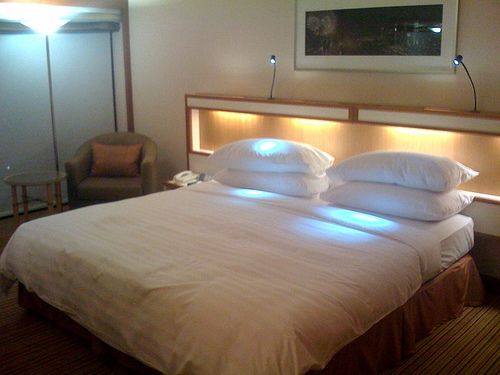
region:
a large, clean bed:
[7, 135, 478, 369]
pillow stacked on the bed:
[204, 135, 477, 220]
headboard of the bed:
[182, 93, 499, 267]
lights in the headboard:
[211, 105, 498, 157]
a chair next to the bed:
[64, 128, 159, 203]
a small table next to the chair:
[3, 168, 66, 219]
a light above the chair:
[20, 16, 72, 35]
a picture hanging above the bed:
[291, 0, 461, 75]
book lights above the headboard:
[266, 51, 481, 112]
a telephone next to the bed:
[171, 170, 198, 185]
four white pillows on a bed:
[198, 138, 479, 226]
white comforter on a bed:
[1, 178, 442, 373]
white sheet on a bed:
[400, 213, 476, 262]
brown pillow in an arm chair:
[89, 138, 141, 178]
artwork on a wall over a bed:
[287, 0, 465, 77]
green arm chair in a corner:
[58, 117, 158, 207]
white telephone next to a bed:
[168, 165, 198, 184]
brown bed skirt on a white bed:
[322, 249, 476, 372]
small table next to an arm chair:
[4, 168, 74, 228]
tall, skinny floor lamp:
[14, 20, 67, 205]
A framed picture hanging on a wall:
[286, 0, 466, 80]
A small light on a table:
[258, 49, 289, 113]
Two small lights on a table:
[259, 50, 489, 120]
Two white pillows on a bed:
[198, 128, 333, 207]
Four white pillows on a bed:
[196, 135, 483, 225]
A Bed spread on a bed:
[16, 175, 482, 370]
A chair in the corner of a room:
[60, 119, 166, 208]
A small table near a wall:
[3, 150, 73, 222]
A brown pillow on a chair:
[62, 120, 173, 208]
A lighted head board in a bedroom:
[179, 83, 498, 219]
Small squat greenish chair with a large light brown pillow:
[57, 114, 173, 218]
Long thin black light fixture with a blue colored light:
[252, 35, 279, 107]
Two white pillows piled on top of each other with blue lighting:
[196, 125, 322, 203]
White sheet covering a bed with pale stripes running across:
[39, 193, 409, 358]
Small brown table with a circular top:
[5, 158, 67, 213]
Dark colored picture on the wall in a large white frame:
[286, 0, 456, 78]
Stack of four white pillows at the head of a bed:
[216, 133, 472, 233]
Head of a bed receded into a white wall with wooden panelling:
[186, 90, 494, 162]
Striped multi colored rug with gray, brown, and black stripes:
[400, 308, 497, 373]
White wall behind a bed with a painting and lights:
[132, 5, 488, 191]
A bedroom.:
[7, 5, 499, 373]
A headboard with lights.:
[182, 92, 497, 247]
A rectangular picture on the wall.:
[294, 4, 459, 74]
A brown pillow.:
[89, 139, 139, 176]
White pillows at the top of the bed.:
[209, 136, 476, 227]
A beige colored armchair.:
[65, 130, 160, 204]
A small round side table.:
[7, 162, 69, 222]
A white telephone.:
[169, 164, 201, 185]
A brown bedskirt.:
[9, 257, 496, 374]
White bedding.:
[5, 136, 467, 373]